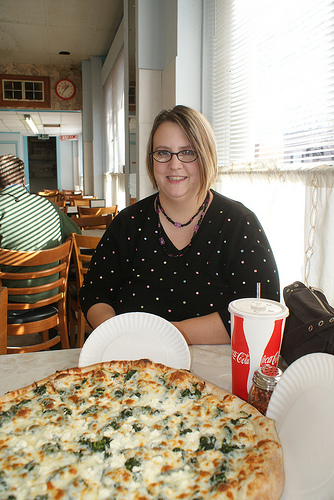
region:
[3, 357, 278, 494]
A very large pizza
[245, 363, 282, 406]
A jar of red pepper flakes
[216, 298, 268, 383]
A paper Coke cup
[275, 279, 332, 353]
A woman's purse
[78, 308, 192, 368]
A paper plate being slid under a pizza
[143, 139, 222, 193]
Glasses on a woman's face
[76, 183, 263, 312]
A woman wearing a lack shirt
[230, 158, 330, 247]
A curtain in a window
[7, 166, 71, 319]
The back of a man sitting in a chair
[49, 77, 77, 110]
A red clock on the wall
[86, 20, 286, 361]
A woman with glasses is sitting at a table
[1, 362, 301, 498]
A pizza with black olives and cheese is sitting on a table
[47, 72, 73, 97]
A red clock is on the wall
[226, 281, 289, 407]
A coca cola cup with a lid and straw and a salt shaker is on the table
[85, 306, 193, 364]
A white paper plate is sitting on the table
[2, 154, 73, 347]
A man in a stripped shirt is sitting in a chair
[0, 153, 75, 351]
A man is sitting in a wooden brown chair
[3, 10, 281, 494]
A woman is sitting at a table with pizza and coca cola cups.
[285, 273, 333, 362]
A black purse is sitting on a table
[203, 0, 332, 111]
The white blinds are closed to keep sun out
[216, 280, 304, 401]
Red and white cup on a table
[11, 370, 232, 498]
Pizza with green and white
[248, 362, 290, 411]
Pepper in a jar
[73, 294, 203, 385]
White plate on a table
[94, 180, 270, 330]
Black shirt with polka dots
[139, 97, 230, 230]
Necklace on a woman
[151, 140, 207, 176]
Glasses on a woman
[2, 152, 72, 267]
Man in a green shirt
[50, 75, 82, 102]
Red clock on a wall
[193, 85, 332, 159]
White blinds in a window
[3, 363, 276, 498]
One large cheese and spinach pizza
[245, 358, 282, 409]
dispenser of crushed red pepper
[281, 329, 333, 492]
white paper plates for serving pizza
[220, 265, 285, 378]
Large paper drink glass displaying Coca-Cola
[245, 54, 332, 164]
white mini blinds at the window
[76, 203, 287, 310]
a multi colored polka dot shirt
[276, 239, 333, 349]
a black handbag with brass rivits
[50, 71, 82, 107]
a clock displaying the time1:35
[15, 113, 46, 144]
a ceiling mounted fluorescent light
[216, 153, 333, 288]
white cafe curtains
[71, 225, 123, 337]
a wooden chair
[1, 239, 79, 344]
a wooden chair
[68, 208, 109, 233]
a wooden chair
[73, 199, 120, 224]
a wooden chair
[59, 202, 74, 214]
a wooden chair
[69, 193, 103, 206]
a wooden chair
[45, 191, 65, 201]
a wooden chair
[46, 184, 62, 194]
a wooden chair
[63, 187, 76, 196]
a wooden chair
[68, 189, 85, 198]
a wooden chair